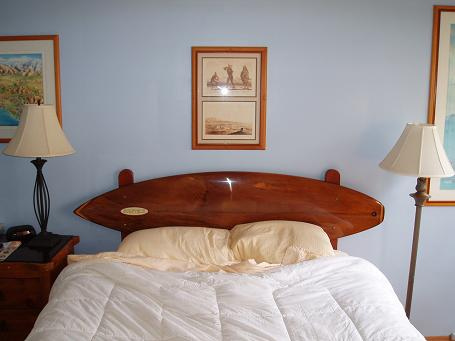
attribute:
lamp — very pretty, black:
[5, 100, 76, 251]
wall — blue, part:
[1, 1, 455, 341]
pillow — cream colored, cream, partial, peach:
[113, 225, 230, 269]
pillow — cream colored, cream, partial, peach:
[229, 218, 334, 264]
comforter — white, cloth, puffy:
[20, 255, 429, 340]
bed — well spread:
[19, 167, 432, 340]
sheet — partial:
[65, 252, 281, 274]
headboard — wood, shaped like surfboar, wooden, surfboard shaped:
[72, 167, 384, 251]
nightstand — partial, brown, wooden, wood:
[1, 234, 80, 341]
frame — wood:
[189, 44, 266, 152]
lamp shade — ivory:
[0, 103, 76, 157]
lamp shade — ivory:
[378, 120, 455, 180]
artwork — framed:
[200, 56, 257, 141]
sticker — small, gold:
[121, 205, 149, 216]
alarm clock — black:
[4, 222, 35, 245]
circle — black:
[370, 210, 379, 219]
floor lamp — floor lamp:
[379, 121, 455, 319]